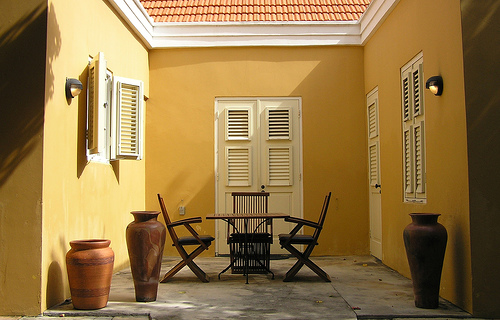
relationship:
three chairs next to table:
[146, 177, 345, 289] [204, 206, 292, 284]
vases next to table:
[124, 198, 176, 305] [213, 203, 281, 275]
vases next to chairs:
[124, 198, 176, 305] [151, 196, 348, 284]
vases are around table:
[125, 210, 166, 302] [203, 202, 303, 285]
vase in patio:
[403, 205, 449, 310] [79, 53, 459, 319]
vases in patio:
[125, 210, 166, 302] [79, 53, 459, 319]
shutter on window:
[87, 50, 102, 152] [82, 57, 113, 165]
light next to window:
[62, 79, 79, 97] [81, 54, 161, 170]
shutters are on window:
[78, 45, 158, 176] [101, 67, 129, 166]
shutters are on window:
[401, 65, 419, 120] [397, 51, 432, 206]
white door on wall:
[366, 83, 382, 264] [363, 0, 473, 317]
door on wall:
[214, 96, 306, 253] [150, 47, 368, 253]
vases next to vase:
[125, 210, 166, 302] [53, 228, 122, 313]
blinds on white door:
[362, 84, 386, 196] [366, 84, 382, 262]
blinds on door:
[220, 100, 257, 191] [214, 96, 304, 254]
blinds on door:
[261, 106, 295, 194] [214, 96, 304, 254]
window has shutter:
[82, 57, 113, 165] [107, 65, 147, 164]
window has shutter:
[82, 57, 113, 165] [80, 44, 112, 164]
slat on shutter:
[268, 113, 292, 120] [263, 105, 298, 145]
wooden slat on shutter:
[228, 116, 250, 120] [228, 110, 288, 185]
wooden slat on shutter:
[268, 116, 294, 125] [260, 103, 296, 142]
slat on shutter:
[120, 92, 135, 98] [110, 75, 143, 155]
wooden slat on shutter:
[121, 94, 142, 102] [113, 75, 143, 161]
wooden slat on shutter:
[118, 101, 143, 111] [110, 75, 143, 155]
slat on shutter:
[122, 116, 135, 121] [116, 80, 142, 158]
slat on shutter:
[121, 135, 140, 141] [111, 74, 144, 158]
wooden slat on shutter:
[122, 92, 134, 152] [110, 75, 143, 155]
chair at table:
[157, 193, 216, 283] [204, 208, 289, 291]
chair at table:
[278, 191, 333, 281] [204, 208, 289, 291]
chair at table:
[222, 186, 279, 278] [204, 208, 289, 291]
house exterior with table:
[1, 1, 498, 317] [199, 209, 287, 268]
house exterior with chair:
[1, 1, 498, 317] [278, 191, 333, 281]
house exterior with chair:
[1, 1, 498, 317] [226, 188, 277, 270]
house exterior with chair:
[1, 1, 498, 317] [155, 192, 217, 284]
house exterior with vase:
[1, 1, 498, 317] [406, 209, 446, 305]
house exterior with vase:
[1, 1, 498, 317] [124, 209, 166, 301]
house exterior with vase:
[1, 1, 498, 317] [64, 238, 115, 310]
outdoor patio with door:
[46, 0, 486, 318] [208, 94, 303, 256]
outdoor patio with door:
[46, 0, 486, 318] [364, 85, 384, 263]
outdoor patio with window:
[46, 0, 486, 318] [401, 50, 425, 200]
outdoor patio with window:
[46, 0, 486, 318] [84, 62, 114, 162]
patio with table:
[55, 0, 478, 317] [201, 208, 303, 228]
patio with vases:
[55, 0, 478, 317] [63, 202, 452, 315]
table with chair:
[206, 213, 287, 285] [277, 192, 334, 282]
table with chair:
[206, 213, 287, 285] [230, 192, 270, 274]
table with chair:
[206, 213, 287, 285] [156, 194, 212, 282]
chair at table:
[144, 178, 222, 296] [204, 206, 292, 284]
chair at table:
[227, 191, 274, 274] [204, 206, 292, 284]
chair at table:
[276, 189, 353, 290] [204, 206, 292, 284]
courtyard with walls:
[51, 0, 479, 317] [38, 0, 470, 317]